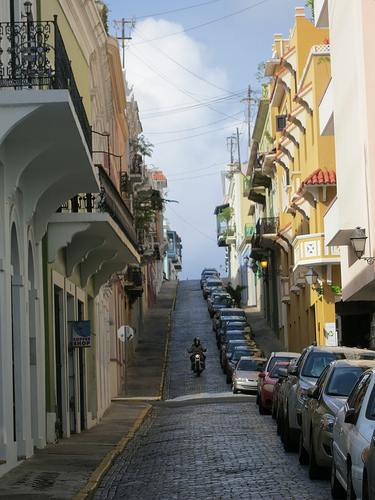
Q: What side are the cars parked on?
A: On the right side.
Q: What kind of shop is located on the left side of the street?
A: Coffee shop.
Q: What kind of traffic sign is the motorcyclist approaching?
A: Stop sign.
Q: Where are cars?
A: On side of the road.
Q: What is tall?
A: Buildings.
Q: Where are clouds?
A: In the sky.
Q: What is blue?
A: Sky.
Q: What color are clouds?
A: White.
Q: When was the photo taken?
A: Daytime.